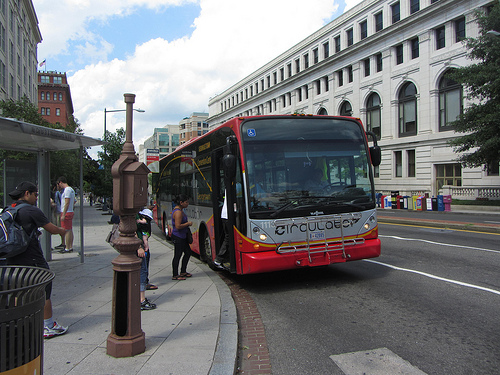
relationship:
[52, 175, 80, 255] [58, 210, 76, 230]
man wearing shorts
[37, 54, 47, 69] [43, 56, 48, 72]
flag on flag pole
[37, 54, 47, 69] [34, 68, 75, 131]
flag on top of building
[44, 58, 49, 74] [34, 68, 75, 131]
pole on top of building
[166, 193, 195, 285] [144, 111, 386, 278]
woman getting on bus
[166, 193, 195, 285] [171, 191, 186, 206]
woman with hair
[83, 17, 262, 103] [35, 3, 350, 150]
clouds in sky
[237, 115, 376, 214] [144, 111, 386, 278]
windshield on a bus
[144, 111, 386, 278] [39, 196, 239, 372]
bus parked by sidewalk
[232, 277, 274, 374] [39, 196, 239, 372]
design by sidewalk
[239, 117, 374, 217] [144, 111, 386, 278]
front window on bus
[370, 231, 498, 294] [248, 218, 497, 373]
paint on road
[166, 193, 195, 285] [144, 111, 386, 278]
woman waiting to get on bus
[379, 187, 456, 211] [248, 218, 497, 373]
newspaper boxes beside road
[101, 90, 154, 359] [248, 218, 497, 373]
pole by road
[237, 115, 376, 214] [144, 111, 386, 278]
windshield on bus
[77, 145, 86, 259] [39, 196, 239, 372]
post on sidewalk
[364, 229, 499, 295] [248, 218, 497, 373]
line on road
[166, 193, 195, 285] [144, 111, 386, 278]
woman waiting outside of bus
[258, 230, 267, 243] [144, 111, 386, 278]
headlight on a bus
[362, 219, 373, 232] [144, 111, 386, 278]
headlight on a bus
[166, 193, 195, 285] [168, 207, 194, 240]
woman wearing blouse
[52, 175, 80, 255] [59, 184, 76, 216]
man wearing t-shirt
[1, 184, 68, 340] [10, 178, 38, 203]
man wearing baseball cap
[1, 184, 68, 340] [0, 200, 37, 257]
man wearing backpack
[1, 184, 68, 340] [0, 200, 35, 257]
man with back pack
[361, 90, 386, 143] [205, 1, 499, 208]
window on building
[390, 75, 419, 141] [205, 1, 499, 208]
window on building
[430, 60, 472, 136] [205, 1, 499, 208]
window on building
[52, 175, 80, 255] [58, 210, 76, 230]
man in shorts